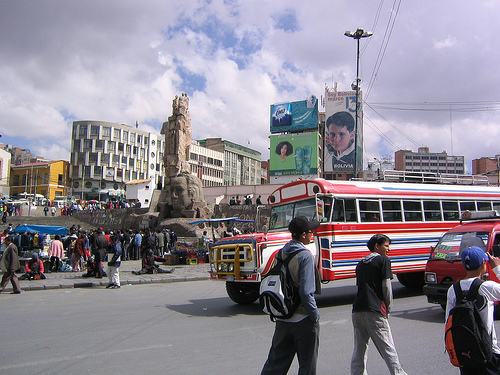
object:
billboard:
[268, 98, 319, 133]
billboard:
[323, 90, 363, 173]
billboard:
[270, 132, 318, 176]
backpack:
[258, 248, 305, 321]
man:
[260, 216, 322, 374]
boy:
[446, 246, 499, 374]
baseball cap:
[461, 246, 490, 268]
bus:
[209, 178, 425, 300]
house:
[11, 159, 69, 201]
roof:
[10, 159, 71, 169]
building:
[69, 120, 166, 207]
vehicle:
[422, 218, 500, 310]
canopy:
[9, 224, 69, 237]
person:
[132, 249, 174, 275]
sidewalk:
[0, 258, 216, 292]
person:
[325, 111, 362, 170]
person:
[274, 141, 293, 161]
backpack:
[443, 278, 491, 368]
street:
[1, 279, 499, 374]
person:
[18, 253, 46, 280]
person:
[92, 229, 108, 278]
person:
[48, 234, 65, 272]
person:
[134, 229, 142, 260]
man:
[1, 235, 21, 294]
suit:
[0, 244, 21, 292]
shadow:
[165, 280, 400, 317]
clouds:
[1, 1, 165, 102]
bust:
[157, 173, 209, 237]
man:
[166, 173, 206, 244]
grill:
[208, 243, 257, 283]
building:
[199, 136, 262, 186]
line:
[0, 315, 355, 373]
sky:
[1, 1, 500, 92]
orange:
[443, 317, 459, 366]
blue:
[204, 20, 239, 47]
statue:
[158, 92, 210, 220]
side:
[257, 181, 500, 280]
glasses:
[305, 228, 314, 234]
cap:
[288, 216, 320, 234]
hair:
[275, 141, 293, 155]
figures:
[172, 93, 190, 115]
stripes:
[9, 183, 70, 190]